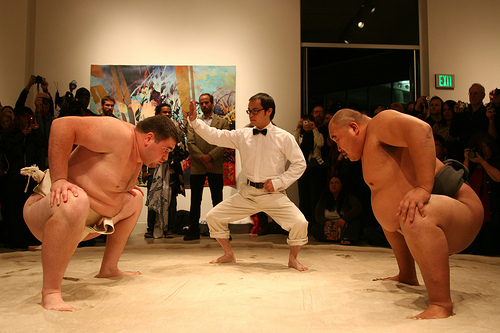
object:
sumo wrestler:
[328, 108, 484, 320]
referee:
[187, 92, 309, 271]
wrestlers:
[17, 95, 490, 320]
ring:
[0, 242, 500, 333]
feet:
[409, 303, 455, 319]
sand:
[131, 240, 332, 249]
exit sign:
[435, 73, 456, 88]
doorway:
[300, 41, 420, 100]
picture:
[89, 64, 237, 187]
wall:
[27, 12, 179, 62]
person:
[293, 115, 330, 242]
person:
[315, 175, 362, 245]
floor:
[134, 234, 198, 244]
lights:
[357, 22, 366, 30]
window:
[302, 4, 424, 45]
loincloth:
[431, 159, 471, 199]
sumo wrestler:
[22, 115, 180, 312]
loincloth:
[20, 163, 115, 242]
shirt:
[186, 116, 307, 191]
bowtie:
[253, 128, 268, 136]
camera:
[35, 75, 42, 84]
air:
[4, 74, 91, 122]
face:
[248, 100, 265, 125]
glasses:
[246, 108, 265, 114]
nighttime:
[302, 4, 422, 96]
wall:
[428, 6, 500, 61]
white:
[186, 116, 308, 246]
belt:
[246, 178, 265, 189]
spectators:
[456, 82, 490, 253]